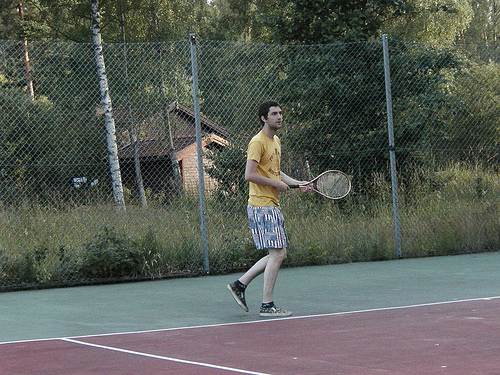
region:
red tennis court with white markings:
[1, 291, 498, 373]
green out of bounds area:
[1, 250, 499, 343]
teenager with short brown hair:
[226, 100, 316, 317]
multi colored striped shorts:
[246, 200, 288, 254]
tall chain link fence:
[1, 32, 498, 291]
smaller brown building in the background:
[103, 132, 248, 207]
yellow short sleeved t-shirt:
[243, 127, 283, 207]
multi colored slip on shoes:
[226, 279, 293, 318]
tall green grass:
[1, 145, 499, 292]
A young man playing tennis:
[11, 6, 496, 362]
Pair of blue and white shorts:
[243, 201, 290, 251]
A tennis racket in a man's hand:
[294, 168, 354, 200]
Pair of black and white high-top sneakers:
[223, 281, 292, 317]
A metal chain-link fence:
[6, 30, 498, 271]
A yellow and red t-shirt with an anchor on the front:
[248, 130, 284, 206]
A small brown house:
[113, 103, 242, 205]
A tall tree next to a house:
[89, 6, 130, 205]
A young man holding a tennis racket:
[219, 97, 356, 320]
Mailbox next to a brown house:
[68, 172, 99, 206]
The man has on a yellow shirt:
[238, 132, 292, 212]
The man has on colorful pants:
[242, 212, 292, 247]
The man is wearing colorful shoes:
[223, 284, 288, 325]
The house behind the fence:
[38, 85, 239, 194]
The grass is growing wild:
[2, 154, 492, 283]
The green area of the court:
[8, 245, 490, 308]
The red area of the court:
[22, 292, 498, 372]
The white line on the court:
[59, 335, 245, 372]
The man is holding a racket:
[309, 157, 370, 213]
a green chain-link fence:
[0, 39, 497, 287]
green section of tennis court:
[1, 245, 497, 341]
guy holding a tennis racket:
[227, 102, 352, 317]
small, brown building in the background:
[77, 100, 243, 202]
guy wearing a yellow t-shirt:
[226, 102, 313, 317]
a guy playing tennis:
[229, 100, 349, 320]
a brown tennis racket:
[286, 171, 351, 196]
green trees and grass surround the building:
[0, 0, 498, 292]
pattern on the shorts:
[246, 207, 281, 248]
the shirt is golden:
[250, 140, 279, 206]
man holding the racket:
[247, 101, 337, 211]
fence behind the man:
[172, 64, 352, 319]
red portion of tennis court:
[0, 292, 499, 374]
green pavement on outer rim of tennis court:
[2, 249, 497, 344]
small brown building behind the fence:
[94, 98, 256, 198]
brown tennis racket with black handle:
[282, 169, 354, 201]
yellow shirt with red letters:
[242, 128, 284, 210]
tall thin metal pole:
[380, 28, 402, 258]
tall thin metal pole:
[188, 31, 212, 273]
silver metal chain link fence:
[1, 31, 498, 288]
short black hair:
[258, 99, 280, 124]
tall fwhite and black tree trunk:
[89, 4, 128, 209]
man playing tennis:
[226, 101, 313, 318]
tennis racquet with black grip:
[288, 169, 351, 198]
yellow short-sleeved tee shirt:
[246, 130, 283, 205]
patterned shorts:
[246, 203, 289, 250]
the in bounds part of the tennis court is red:
[1, 296, 497, 373]